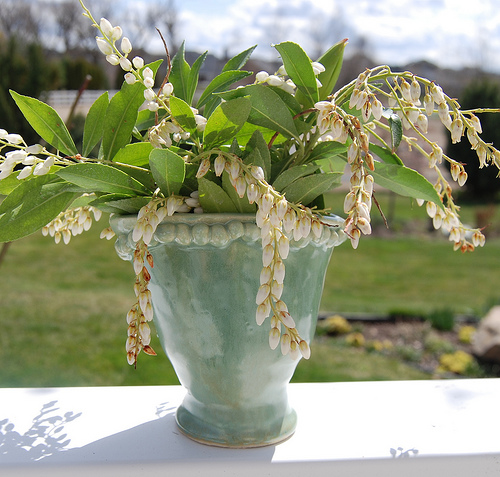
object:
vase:
[111, 214, 349, 452]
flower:
[32, 155, 57, 178]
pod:
[195, 158, 211, 178]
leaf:
[53, 163, 154, 198]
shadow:
[0, 398, 85, 474]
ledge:
[0, 377, 499, 475]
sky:
[0, 0, 500, 72]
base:
[173, 404, 300, 449]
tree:
[1, 1, 104, 88]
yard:
[1, 205, 500, 389]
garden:
[317, 317, 499, 378]